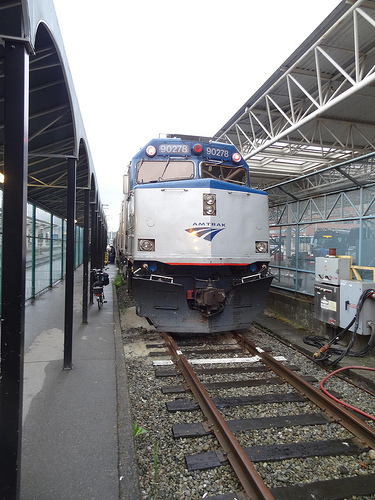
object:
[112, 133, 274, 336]
train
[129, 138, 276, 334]
front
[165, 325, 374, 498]
tracks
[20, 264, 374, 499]
ground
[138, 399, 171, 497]
rocks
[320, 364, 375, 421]
hose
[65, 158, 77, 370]
pole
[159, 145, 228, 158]
number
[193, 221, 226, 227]
word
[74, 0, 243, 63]
sky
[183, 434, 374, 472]
tie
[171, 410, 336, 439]
tie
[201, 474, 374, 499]
tie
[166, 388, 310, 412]
tie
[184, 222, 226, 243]
logo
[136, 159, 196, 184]
window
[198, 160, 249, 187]
window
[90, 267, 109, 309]
bicycle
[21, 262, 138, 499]
platform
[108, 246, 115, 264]
passenger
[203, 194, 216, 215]
headlight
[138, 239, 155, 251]
headlight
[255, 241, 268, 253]
headlight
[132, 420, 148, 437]
plant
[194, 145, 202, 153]
light